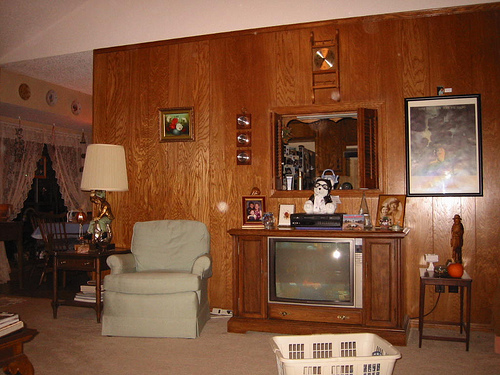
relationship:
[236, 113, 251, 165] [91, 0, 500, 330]
plaques on panelled wall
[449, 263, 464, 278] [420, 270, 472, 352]
pumpkin on table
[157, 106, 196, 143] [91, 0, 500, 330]
painting on panelled wall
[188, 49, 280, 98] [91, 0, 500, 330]
wooden panels on panelled wall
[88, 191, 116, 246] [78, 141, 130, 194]
lamp with shade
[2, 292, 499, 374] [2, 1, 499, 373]
carpet in livingroom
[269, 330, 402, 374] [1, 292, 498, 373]
basket on floor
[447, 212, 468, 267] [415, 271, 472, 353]
statue on table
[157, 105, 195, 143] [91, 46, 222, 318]
painting on wall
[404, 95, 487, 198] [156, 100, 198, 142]
picture on a picture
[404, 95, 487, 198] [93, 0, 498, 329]
picture on a panelled wall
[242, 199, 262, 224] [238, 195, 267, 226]
portrait in a frame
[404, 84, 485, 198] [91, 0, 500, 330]
picture on panelled wall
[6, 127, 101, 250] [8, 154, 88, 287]
curtains in a window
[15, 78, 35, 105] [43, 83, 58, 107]
plate hanging on plate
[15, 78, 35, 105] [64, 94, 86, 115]
plate hanging on plate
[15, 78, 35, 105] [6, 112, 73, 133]
plate hanging on wall